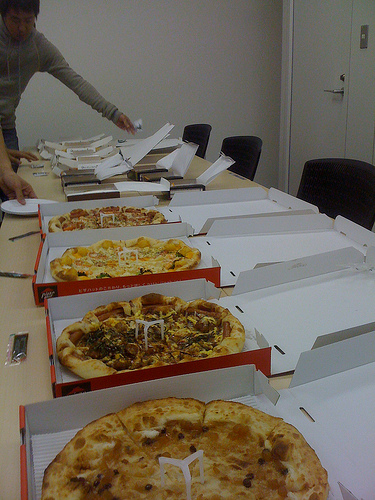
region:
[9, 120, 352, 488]
this is a table top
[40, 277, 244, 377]
this is a pizza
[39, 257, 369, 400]
this is a pizza box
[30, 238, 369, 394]
pizza sitting in pizza box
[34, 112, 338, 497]
this is a row of pizzas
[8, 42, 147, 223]
this is a person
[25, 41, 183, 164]
this is an arm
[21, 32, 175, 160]
person has arm extended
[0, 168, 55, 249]
this is a plate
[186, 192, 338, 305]
white lid on pizza box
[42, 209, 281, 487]
A row of pizza's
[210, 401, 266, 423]
Crust of a pizza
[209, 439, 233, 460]
Cheese on a pizza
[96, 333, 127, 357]
Toppings on top of a pizza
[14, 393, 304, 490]
A pizza in a box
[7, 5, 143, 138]
A person reaching for something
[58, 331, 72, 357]
Crust of a pizza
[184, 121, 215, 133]
A chair near a table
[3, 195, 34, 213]
A white plate in a man's hand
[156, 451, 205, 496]
An object in middle of the pizza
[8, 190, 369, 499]
several pizzas in white cardboard boxes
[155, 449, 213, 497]
white plastic protective piece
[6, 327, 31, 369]
one rectangular packet of soy sauce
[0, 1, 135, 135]
person wearing long sleeved gray shirt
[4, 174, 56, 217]
one hand holding circular white plate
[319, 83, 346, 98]
one shiny metal door handle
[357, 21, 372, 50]
one light metal switchplate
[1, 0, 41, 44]
one man with short dark hair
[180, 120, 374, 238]
three dark chairs pushed in next to table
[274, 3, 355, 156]
one closed white office door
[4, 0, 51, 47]
the head of a man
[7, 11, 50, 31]
the eye of a man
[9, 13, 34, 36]
the nose of a man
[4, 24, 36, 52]
the mouth of a man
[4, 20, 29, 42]
the cheek of a man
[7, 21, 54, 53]
the chin of a man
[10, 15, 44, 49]
the lips of a man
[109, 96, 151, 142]
the hand of a man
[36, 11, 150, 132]
the arm of a man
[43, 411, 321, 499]
Pizza in a box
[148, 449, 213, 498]
Plastic, white tripod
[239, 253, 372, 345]
Pizza box lid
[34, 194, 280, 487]
Four pizzas on a table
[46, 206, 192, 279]
Two pizzas on a table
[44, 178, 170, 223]
Pepperoni pizza on a table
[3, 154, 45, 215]
Hand holding a white plate